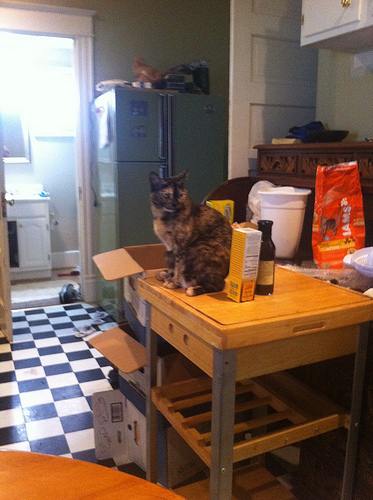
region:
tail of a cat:
[193, 285, 215, 299]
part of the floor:
[40, 403, 75, 438]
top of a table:
[37, 472, 81, 494]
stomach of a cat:
[184, 219, 223, 253]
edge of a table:
[61, 448, 99, 477]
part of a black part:
[22, 396, 49, 418]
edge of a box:
[90, 335, 128, 380]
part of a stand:
[207, 413, 232, 463]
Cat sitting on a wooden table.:
[148, 168, 231, 296]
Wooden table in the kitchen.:
[135, 274, 371, 497]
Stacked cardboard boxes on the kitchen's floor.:
[85, 243, 204, 485]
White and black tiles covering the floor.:
[5, 356, 87, 436]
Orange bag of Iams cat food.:
[312, 161, 365, 269]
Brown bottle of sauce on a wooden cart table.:
[255, 219, 275, 293]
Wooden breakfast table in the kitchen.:
[0, 450, 184, 498]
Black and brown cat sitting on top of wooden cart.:
[147, 169, 371, 348]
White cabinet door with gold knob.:
[298, 1, 371, 49]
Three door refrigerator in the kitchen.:
[94, 85, 228, 320]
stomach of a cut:
[194, 226, 221, 254]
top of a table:
[46, 459, 84, 485]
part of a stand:
[205, 468, 235, 498]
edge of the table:
[97, 458, 124, 477]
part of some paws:
[164, 274, 185, 299]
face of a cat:
[157, 175, 189, 212]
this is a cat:
[144, 173, 224, 293]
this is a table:
[1, 453, 42, 494]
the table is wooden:
[10, 455, 51, 490]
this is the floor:
[2, 363, 65, 430]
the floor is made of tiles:
[4, 358, 77, 438]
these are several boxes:
[118, 258, 148, 458]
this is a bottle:
[259, 219, 276, 298]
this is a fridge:
[180, 115, 222, 178]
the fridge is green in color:
[191, 124, 226, 173]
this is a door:
[1, 255, 13, 343]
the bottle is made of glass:
[262, 223, 274, 292]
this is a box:
[230, 228, 256, 301]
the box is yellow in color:
[232, 238, 240, 281]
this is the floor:
[33, 310, 64, 412]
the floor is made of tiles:
[32, 317, 57, 403]